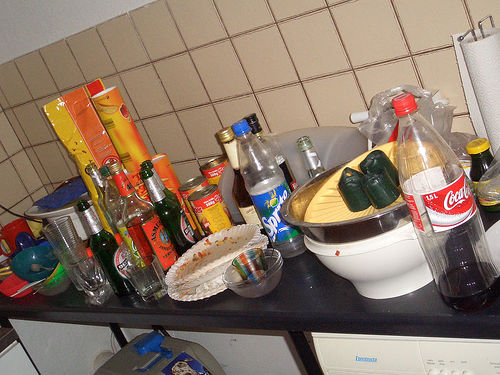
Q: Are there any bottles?
A: Yes, there is a bottle.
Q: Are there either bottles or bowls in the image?
A: Yes, there is a bottle.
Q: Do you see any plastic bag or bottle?
A: Yes, there is a plastic bottle.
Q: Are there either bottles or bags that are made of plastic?
A: Yes, the bottle is made of plastic.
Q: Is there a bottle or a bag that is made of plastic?
A: Yes, the bottle is made of plastic.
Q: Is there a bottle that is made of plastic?
A: Yes, there is a bottle that is made of plastic.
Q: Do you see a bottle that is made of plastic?
A: Yes, there is a bottle that is made of plastic.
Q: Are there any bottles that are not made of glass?
A: Yes, there is a bottle that is made of plastic.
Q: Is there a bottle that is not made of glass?
A: Yes, there is a bottle that is made of plastic.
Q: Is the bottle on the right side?
A: Yes, the bottle is on the right of the image.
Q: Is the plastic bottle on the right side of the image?
A: Yes, the bottle is on the right of the image.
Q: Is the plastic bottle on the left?
A: No, the bottle is on the right of the image.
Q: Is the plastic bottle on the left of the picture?
A: No, the bottle is on the right of the image.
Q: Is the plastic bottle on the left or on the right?
A: The bottle is on the right of the image.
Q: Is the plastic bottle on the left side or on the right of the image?
A: The bottle is on the right of the image.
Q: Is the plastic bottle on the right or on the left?
A: The bottle is on the right of the image.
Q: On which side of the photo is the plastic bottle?
A: The bottle is on the right of the image.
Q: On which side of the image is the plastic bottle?
A: The bottle is on the right of the image.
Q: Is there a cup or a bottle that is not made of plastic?
A: No, there is a bottle but it is made of plastic.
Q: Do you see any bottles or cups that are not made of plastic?
A: No, there is a bottle but it is made of plastic.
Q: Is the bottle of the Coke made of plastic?
A: Yes, the bottle is made of plastic.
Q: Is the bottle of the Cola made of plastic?
A: Yes, the bottle is made of plastic.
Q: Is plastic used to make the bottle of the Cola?
A: Yes, the bottle is made of plastic.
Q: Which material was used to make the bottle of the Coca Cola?
A: The bottle is made of plastic.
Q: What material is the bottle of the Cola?
A: The bottle is made of plastic.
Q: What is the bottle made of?
A: The bottle is made of plastic.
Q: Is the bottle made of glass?
A: No, the bottle is made of plastic.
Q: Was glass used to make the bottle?
A: No, the bottle is made of plastic.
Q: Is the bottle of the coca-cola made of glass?
A: No, the bottle is made of plastic.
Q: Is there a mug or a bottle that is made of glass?
A: No, there is a bottle but it is made of plastic.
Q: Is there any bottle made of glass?
A: No, there is a bottle but it is made of plastic.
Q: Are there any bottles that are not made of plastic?
A: No, there is a bottle but it is made of plastic.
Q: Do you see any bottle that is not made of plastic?
A: No, there is a bottle but it is made of plastic.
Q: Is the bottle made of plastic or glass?
A: The bottle is made of plastic.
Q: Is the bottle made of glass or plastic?
A: The bottle is made of plastic.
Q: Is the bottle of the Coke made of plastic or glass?
A: The bottle is made of plastic.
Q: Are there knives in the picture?
A: No, there are no knives.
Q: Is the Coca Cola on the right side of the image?
A: Yes, the Coca Cola is on the right of the image.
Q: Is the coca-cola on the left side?
A: No, the coca-cola is on the right of the image.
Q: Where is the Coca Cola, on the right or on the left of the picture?
A: The Coca Cola is on the right of the image.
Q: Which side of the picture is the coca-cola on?
A: The coca-cola is on the right of the image.